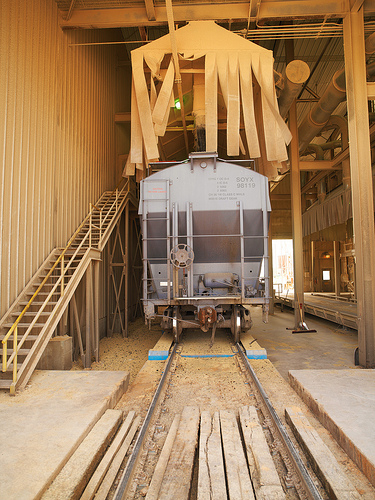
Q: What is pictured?
A: Train.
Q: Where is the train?
A: On tracks.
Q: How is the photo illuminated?
A: Sunlight.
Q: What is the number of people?
A: Zero.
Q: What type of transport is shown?
A: A train.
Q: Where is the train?
A: On tracks.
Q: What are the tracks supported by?
A: Wood.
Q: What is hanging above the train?
A: A tent.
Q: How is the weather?
A: Sunny.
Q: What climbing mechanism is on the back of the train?
A: A ladder.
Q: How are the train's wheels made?
A: Of steel.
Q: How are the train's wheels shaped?
A: Roundly.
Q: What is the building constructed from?
A: Wood.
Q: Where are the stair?
A: On the left side of the picture.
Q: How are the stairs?
A: Very narrow.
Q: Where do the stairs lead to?
A: The upper level.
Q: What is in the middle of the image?
A: The tracks.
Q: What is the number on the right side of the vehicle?
A: 98119.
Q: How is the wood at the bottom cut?
A: Into narrow boards.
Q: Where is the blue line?
A: In front of the train.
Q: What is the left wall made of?
A: Metal.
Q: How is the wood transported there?
A: By the gray carrier.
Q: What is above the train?
A: A tent.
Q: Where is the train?
A: On the tracks.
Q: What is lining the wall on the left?
A: Stairs.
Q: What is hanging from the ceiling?
A: Pipes.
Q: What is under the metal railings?
A: Wood.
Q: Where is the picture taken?
A: A factory.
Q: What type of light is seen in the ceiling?
A: Green.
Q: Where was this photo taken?
A: Train depot.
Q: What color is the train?
A: Grey.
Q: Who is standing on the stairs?
A: No one.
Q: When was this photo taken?
A: Daytime.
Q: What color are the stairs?
A: Tan.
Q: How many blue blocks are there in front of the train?
A: Three.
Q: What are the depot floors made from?
A: Wood.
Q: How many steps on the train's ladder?
A: Seven.